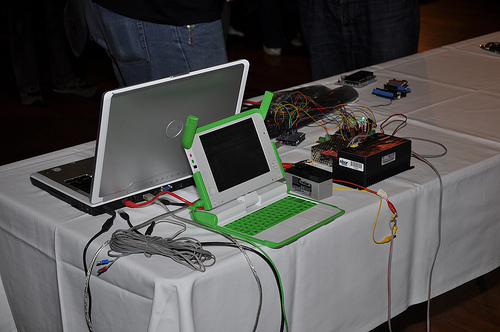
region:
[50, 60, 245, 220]
silver and white laptop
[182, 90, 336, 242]
green and white laptop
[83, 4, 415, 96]
people standing next to table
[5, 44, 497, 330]
white tablecloth on the table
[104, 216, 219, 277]
gray bundled cord on the table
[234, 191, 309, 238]
green keys with black lettering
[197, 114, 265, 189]
screen of the white and green laptop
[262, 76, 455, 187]
multi colored wires on the table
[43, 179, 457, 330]
cords hanging off the table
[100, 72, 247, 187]
lid of the white and silver laptop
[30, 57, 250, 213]
A silver laptop resting on a table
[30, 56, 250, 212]
A silver laptop with white trimmings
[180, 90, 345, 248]
A white and green small laptop computer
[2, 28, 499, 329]
A rectangular table with a white tablecloth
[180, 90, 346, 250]
A laptop with the screen content almost visible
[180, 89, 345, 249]
A small laptop computer with a green keyboard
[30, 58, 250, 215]
A silver computer with black keys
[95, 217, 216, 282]
A tied up gray clable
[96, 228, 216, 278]
A long grey cable with red and blue ends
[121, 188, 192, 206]
A red cable connected to a computer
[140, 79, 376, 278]
a green and white laptop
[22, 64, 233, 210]
a silver laptop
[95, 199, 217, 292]
gray cords for laptop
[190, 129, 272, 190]
the screen is dark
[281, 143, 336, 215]
this looks like a battery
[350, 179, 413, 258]
red and yellow cords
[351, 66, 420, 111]
a blue part for laptop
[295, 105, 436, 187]
parts for the laptop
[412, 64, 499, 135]
the table cloth is white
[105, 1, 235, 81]
the person is wearing jeans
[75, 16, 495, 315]
white table cloth on table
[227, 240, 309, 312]
green wires hanging from laptop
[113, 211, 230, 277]
gray wires bunched on table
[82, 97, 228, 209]
silver laptop on table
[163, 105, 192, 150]
round dell logo on laptop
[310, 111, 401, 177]
electronic box on table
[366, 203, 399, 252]
yellow wire on table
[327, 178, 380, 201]
red wire on table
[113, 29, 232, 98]
blue denim jeans on man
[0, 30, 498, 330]
a long folding table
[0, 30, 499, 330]
a large white tablecloth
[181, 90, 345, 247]
a white and green laptop computer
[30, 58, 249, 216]
a silver laptop computer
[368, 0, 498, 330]
a dark hardwood floor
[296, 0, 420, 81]
a person standing by the table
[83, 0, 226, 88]
a person standing by the table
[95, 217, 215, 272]
a bundle of gray wires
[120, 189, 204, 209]
a red wire in a laptop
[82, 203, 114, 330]
a power cord in a laptop